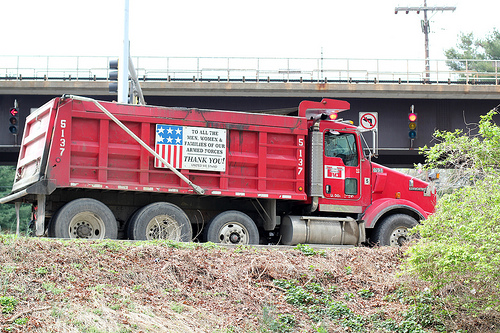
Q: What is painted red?
A: The dump truck.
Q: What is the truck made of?
A: Metal.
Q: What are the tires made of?
A: Rubber.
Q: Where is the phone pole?
A: Behind the overpass.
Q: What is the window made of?
A: Glass.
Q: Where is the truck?
A: Next to a bridge.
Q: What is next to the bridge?
A: A red truck.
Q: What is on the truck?
A: A sign.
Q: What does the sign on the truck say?
A: Thank you.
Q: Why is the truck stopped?
A: The light is red.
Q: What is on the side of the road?
A: A bush.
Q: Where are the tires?
A: On the truck.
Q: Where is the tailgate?
A: On the truck.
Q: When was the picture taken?
A: Daytime.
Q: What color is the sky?
A: White.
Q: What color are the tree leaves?
A: Green.